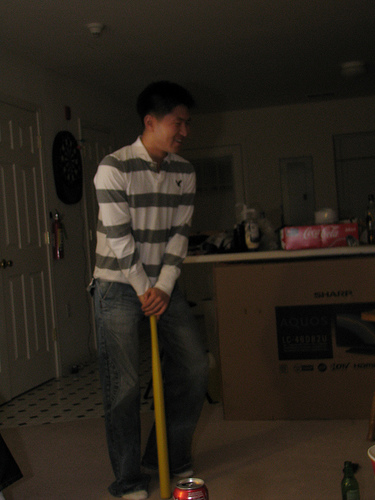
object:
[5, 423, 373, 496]
floor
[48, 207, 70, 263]
hydrant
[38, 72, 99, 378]
wall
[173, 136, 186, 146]
smiling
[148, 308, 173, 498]
stick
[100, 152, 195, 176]
stripe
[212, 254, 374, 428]
box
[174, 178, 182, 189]
logo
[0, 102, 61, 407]
door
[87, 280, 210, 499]
jeans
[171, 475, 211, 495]
can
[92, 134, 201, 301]
shirt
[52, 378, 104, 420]
linoleum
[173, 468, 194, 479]
sock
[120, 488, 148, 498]
sock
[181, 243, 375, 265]
counter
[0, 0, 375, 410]
kitchen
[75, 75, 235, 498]
man